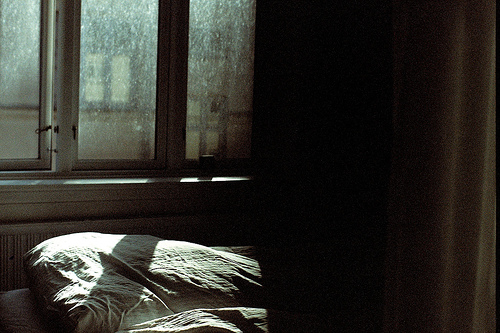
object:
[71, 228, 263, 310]
pillow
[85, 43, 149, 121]
window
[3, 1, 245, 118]
building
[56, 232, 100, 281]
light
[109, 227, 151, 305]
shadows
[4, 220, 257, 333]
bed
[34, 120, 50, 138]
latch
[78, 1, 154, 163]
glass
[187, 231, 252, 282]
sheet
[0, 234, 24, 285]
slats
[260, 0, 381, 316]
wall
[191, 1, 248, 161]
windowpane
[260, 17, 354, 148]
opposite side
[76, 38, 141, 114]
doors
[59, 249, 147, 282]
cloth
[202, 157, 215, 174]
water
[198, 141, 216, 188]
glass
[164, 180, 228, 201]
shadow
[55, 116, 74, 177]
wood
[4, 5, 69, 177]
pane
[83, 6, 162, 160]
pane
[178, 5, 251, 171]
pane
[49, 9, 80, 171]
trim